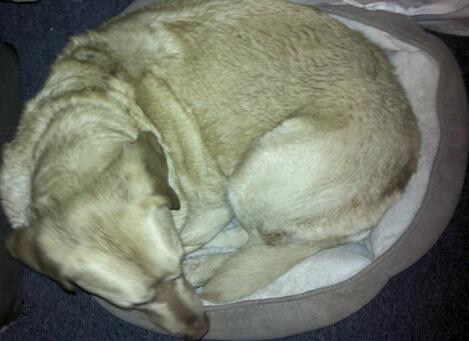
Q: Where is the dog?
A: In his bed.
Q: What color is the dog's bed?
A: Beige and white.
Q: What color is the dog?
A: Tan.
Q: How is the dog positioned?
A: Curled up in his bed.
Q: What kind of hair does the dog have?
A: Short.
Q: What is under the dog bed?
A: Carpet.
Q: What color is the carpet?
A: Dark blue.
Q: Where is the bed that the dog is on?
A: Pillow as a bed.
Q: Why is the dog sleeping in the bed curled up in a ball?
A: To sleep better.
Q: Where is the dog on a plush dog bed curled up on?
A: Dog bed.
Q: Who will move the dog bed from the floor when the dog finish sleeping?
A: The owner.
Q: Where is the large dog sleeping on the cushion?
A: On the floor.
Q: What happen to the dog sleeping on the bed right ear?
A: Dog ear is pointing down.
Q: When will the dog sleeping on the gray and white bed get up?
A: After the dog is awake.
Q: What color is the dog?
A: White.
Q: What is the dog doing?
A: Sleeping.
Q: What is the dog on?
A: Dog bed.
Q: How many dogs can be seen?
A: 1.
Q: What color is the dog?
A: White.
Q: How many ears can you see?
A: 2.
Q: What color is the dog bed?
A: White, grey.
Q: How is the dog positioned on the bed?
A: Curled.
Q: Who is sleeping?
A: Dog.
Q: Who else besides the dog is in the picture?
A: No one.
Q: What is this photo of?
A: Dog laying down.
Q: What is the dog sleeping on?
A: Gray and white dog bed cushion.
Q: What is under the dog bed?
A: Blue carpeting.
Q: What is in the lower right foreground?
A: Dog cushion and blue carpet in bottom right.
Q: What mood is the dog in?
A: Sleepy.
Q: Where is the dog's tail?
A: Tucked under him.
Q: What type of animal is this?
A: A dog.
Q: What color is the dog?
A: Cream.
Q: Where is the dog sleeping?
A: Dog bed.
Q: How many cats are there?
A: None.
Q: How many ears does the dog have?
A: 2.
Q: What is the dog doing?
A: Sleeping.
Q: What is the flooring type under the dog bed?
A: Carpeting.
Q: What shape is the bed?
A: Round.